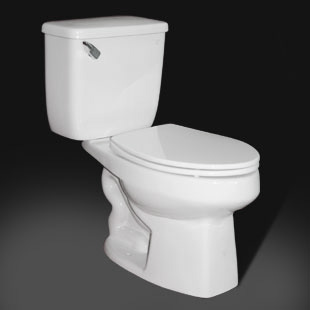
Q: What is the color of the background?
A: Black.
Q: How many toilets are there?
A: One.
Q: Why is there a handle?
A: To flush the toilet.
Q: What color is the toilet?
A: White.